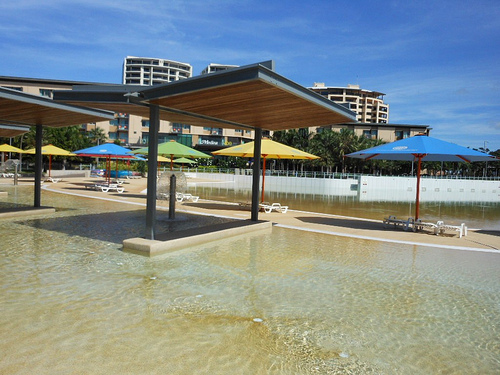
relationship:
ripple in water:
[220, 352, 245, 369] [0, 182, 498, 373]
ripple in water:
[148, 345, 194, 374] [0, 182, 498, 373]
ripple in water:
[266, 351, 281, 372] [0, 182, 498, 373]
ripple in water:
[301, 319, 310, 349] [0, 182, 498, 373]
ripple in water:
[450, 297, 461, 318] [0, 182, 498, 373]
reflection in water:
[184, 162, 359, 204] [0, 182, 498, 373]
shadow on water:
[18, 195, 248, 241] [0, 182, 498, 373]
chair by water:
[91, 159, 146, 194] [0, 182, 498, 373]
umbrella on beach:
[211, 136, 318, 160] [3, 176, 498, 252]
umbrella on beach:
[343, 132, 497, 172] [296, 202, 494, 311]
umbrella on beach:
[134, 134, 236, 174] [12, 173, 497, 346]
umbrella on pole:
[343, 132, 499, 162] [412, 153, 424, 220]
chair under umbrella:
[374, 209, 469, 248] [347, 132, 488, 224]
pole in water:
[168, 174, 177, 220] [97, 202, 289, 284]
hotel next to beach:
[157, 112, 257, 172] [4, 164, 498, 363]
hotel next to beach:
[42, 111, 152, 172] [4, 164, 498, 363]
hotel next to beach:
[1, 72, 133, 102] [4, 164, 498, 363]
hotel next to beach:
[1, 120, 36, 187] [4, 164, 498, 363]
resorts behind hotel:
[34, 77, 499, 367] [118, 50, 404, 137]